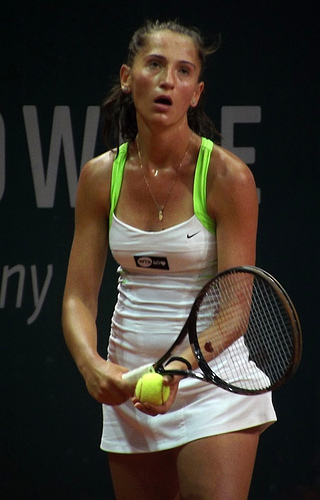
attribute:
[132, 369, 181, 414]
ball — yellow, freen, fuzzy, tennis ball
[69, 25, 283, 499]
woman — sweaty, sweating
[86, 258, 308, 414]
racket — white, brown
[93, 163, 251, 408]
dress — white, unpleated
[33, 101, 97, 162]
letters — white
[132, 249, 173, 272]
logo — black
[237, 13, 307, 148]
barrier — black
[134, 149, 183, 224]
necklace — gold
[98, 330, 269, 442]
skirt — short, white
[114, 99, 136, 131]
hair — back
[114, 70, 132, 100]
earlobe — peirced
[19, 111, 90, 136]
writing — white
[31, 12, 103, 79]
wall — black, white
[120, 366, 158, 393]
handle — white